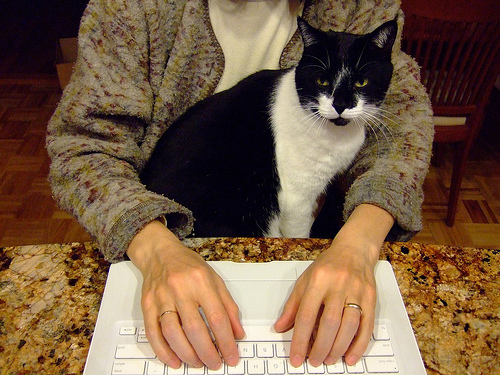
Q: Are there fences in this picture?
A: No, there are no fences.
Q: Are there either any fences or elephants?
A: No, there are no fences or elephants.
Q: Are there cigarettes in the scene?
A: No, there are no cigarettes.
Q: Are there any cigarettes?
A: No, there are no cigarettes.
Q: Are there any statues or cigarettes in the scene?
A: No, there are no cigarettes or statues.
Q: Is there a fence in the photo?
A: No, there are no fences.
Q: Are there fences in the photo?
A: No, there are no fences.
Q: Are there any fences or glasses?
A: No, there are no fences or glasses.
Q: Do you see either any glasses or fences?
A: No, there are no fences or glasses.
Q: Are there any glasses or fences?
A: No, there are no fences or glasses.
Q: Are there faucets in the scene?
A: No, there are no faucets.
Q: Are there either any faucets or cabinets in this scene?
A: No, there are no faucets or cabinets.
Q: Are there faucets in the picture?
A: No, there are no faucets.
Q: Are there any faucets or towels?
A: No, there are no faucets or towels.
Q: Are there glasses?
A: No, there are no glasses.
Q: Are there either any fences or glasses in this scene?
A: No, there are no glasses or fences.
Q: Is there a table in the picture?
A: Yes, there is a table.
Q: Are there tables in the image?
A: Yes, there is a table.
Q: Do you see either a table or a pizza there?
A: Yes, there is a table.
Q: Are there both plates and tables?
A: No, there is a table but no plates.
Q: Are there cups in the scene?
A: No, there are no cups.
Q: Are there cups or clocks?
A: No, there are no cups or clocks.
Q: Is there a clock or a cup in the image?
A: No, there are no cups or clocks.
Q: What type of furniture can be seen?
A: The furniture is a table.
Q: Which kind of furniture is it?
A: The piece of furniture is a table.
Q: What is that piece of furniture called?
A: This is a table.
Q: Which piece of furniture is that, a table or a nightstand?
A: This is a table.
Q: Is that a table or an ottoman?
A: That is a table.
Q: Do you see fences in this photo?
A: No, there are no fences.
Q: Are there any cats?
A: Yes, there is a cat.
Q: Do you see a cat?
A: Yes, there is a cat.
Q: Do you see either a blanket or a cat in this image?
A: Yes, there is a cat.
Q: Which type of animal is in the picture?
A: The animal is a cat.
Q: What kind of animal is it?
A: The animal is a cat.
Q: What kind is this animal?
A: This is a cat.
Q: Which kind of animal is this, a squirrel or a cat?
A: This is a cat.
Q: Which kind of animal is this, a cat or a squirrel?
A: This is a cat.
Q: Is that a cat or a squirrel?
A: That is a cat.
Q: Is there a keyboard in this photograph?
A: Yes, there is a keyboard.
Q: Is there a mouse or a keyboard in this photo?
A: Yes, there is a keyboard.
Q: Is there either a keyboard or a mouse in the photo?
A: Yes, there is a keyboard.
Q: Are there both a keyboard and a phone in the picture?
A: No, there is a keyboard but no phones.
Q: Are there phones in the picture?
A: No, there are no phones.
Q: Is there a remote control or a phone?
A: No, there are no phones or remote controls.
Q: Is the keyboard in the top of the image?
A: No, the keyboard is in the bottom of the image.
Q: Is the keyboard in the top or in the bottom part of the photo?
A: The keyboard is in the bottom of the image.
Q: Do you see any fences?
A: No, there are no fences.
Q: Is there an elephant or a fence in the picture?
A: No, there are no fences or elephants.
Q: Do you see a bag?
A: No, there are no bags.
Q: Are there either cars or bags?
A: No, there are no bags or cars.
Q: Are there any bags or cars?
A: No, there are no bags or cars.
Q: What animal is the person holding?
A: The person is holding the cat.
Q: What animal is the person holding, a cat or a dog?
A: The person is holding a cat.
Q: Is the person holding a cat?
A: Yes, the person is holding a cat.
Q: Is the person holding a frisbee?
A: No, the person is holding a cat.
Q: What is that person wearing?
A: The person is wearing a shirt.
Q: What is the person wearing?
A: The person is wearing a shirt.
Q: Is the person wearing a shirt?
A: Yes, the person is wearing a shirt.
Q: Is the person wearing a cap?
A: No, the person is wearing a shirt.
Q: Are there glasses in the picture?
A: No, there are no glasses.